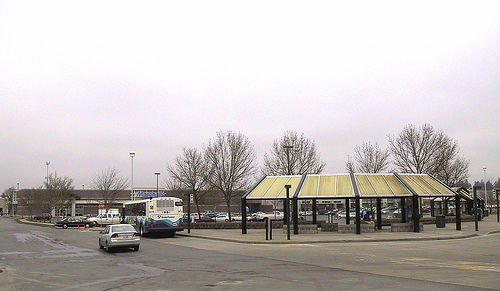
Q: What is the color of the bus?
A: White and blue.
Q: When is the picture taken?
A: Daytime.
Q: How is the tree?
A: Without leaves.